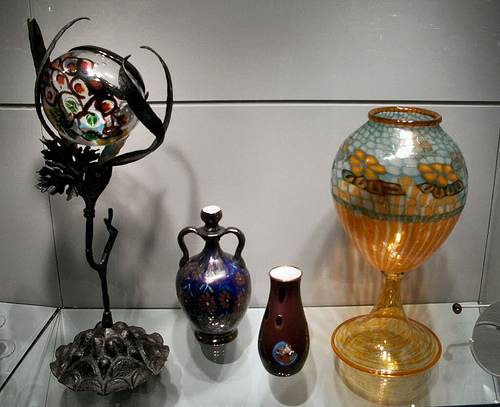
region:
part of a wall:
[254, 8, 336, 65]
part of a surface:
[214, 359, 261, 396]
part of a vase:
[264, 315, 310, 352]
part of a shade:
[287, 383, 311, 396]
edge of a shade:
[261, 377, 276, 402]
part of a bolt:
[438, 281, 473, 336]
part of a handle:
[170, 232, 209, 262]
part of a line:
[234, 74, 286, 136]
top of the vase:
[267, 271, 298, 288]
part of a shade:
[323, 255, 360, 299]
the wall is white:
[0, 0, 499, 320]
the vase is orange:
[323, 95, 474, 391]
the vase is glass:
[310, 80, 475, 382]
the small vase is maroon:
[250, 250, 317, 385]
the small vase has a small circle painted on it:
[270, 336, 301, 369]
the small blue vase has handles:
[170, 200, 255, 360]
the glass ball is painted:
[37, 41, 148, 156]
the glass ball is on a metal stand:
[29, 41, 155, 166]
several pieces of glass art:
[23, 26, 476, 405]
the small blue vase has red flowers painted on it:
[145, 192, 253, 368]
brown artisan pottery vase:
[251, 260, 321, 377]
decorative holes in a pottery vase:
[272, 287, 313, 378]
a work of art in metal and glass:
[6, 18, 173, 398]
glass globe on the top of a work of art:
[3, 9, 199, 209]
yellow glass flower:
[341, 142, 393, 200]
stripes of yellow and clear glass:
[359, 214, 433, 265]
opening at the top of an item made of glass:
[362, 95, 456, 144]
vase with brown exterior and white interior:
[258, 257, 317, 327]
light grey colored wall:
[189, 81, 294, 185]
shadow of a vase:
[250, 358, 339, 405]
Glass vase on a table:
[326, 91, 471, 378]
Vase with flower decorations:
[326, 97, 470, 388]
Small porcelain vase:
[258, 260, 315, 382]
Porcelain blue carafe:
[169, 195, 255, 347]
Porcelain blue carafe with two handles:
[168, 196, 253, 351]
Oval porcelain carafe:
[175, 201, 257, 353]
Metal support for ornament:
[0, 15, 175, 404]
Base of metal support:
[41, 319, 183, 403]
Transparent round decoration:
[36, 41, 157, 151]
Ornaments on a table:
[21, 15, 473, 397]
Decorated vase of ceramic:
[255, 255, 311, 380]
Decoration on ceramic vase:
[267, 337, 297, 362]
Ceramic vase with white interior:
[255, 260, 313, 378]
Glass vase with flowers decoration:
[322, 91, 470, 381]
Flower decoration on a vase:
[338, 145, 463, 192]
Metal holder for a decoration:
[20, 10, 185, 400]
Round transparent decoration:
[32, 41, 148, 149]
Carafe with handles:
[170, 201, 253, 344]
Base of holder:
[50, 316, 175, 396]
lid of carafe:
[196, 202, 225, 232]